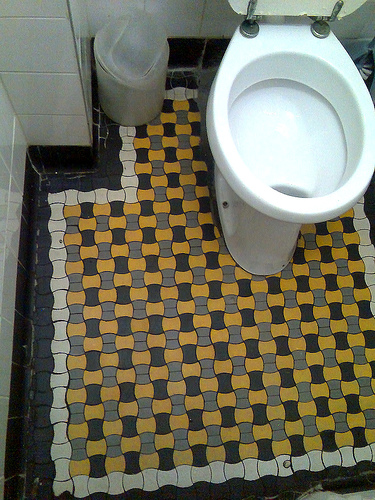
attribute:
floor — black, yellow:
[8, 150, 351, 499]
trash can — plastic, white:
[84, 6, 168, 130]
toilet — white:
[196, 17, 364, 279]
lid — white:
[227, 0, 361, 40]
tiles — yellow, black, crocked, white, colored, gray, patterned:
[41, 242, 91, 369]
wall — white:
[7, 9, 113, 176]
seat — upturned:
[204, 28, 373, 217]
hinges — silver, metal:
[240, 8, 354, 25]